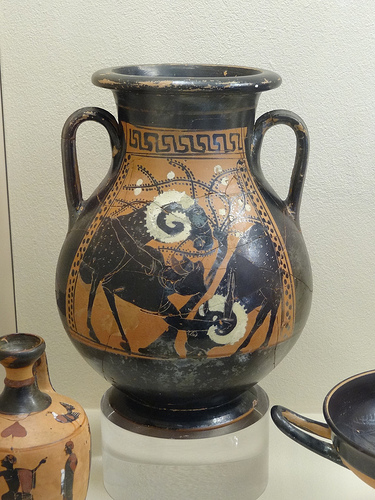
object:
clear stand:
[101, 406, 268, 499]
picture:
[83, 139, 284, 362]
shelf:
[0, 301, 373, 498]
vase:
[53, 61, 314, 441]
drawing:
[58, 437, 88, 500]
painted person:
[0, 452, 46, 500]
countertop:
[85, 407, 374, 499]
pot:
[47, 60, 329, 438]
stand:
[99, 383, 270, 500]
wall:
[139, 0, 272, 76]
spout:
[0, 330, 48, 413]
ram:
[142, 188, 197, 245]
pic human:
[82, 211, 214, 355]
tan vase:
[0, 333, 92, 497]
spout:
[88, 64, 282, 145]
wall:
[282, 23, 359, 93]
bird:
[43, 400, 82, 429]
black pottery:
[53, 63, 312, 440]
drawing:
[146, 187, 213, 259]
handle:
[57, 105, 126, 220]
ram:
[198, 293, 249, 346]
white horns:
[198, 292, 250, 347]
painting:
[75, 158, 282, 361]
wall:
[315, 80, 366, 277]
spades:
[0, 420, 28, 438]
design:
[66, 122, 295, 360]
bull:
[77, 215, 226, 356]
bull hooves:
[119, 340, 132, 356]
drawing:
[71, 117, 298, 357]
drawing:
[0, 453, 48, 499]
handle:
[247, 108, 311, 223]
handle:
[269, 403, 340, 464]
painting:
[60, 440, 78, 500]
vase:
[270, 367, 372, 500]